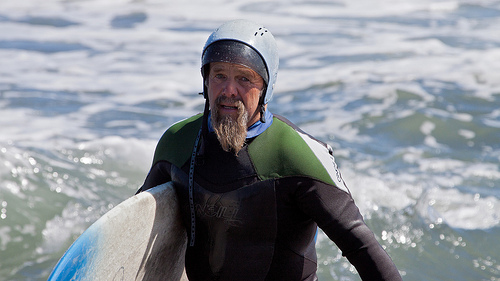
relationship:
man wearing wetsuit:
[139, 25, 402, 280] [132, 114, 401, 280]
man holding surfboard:
[139, 25, 402, 280] [48, 185, 189, 281]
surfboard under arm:
[48, 185, 189, 281] [139, 129, 168, 189]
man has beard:
[139, 25, 402, 280] [214, 110, 250, 154]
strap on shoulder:
[185, 113, 204, 245] [162, 122, 202, 153]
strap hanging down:
[185, 113, 204, 245] [192, 242, 193, 243]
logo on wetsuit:
[193, 198, 253, 221] [132, 114, 401, 280]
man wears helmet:
[139, 25, 402, 280] [196, 18, 276, 105]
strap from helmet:
[185, 113, 204, 245] [196, 18, 276, 105]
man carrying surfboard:
[139, 25, 402, 280] [48, 185, 189, 281]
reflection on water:
[4, 151, 114, 204] [1, 1, 497, 280]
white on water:
[5, 0, 497, 165] [1, 1, 497, 280]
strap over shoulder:
[185, 113, 204, 245] [162, 122, 202, 153]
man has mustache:
[139, 25, 402, 280] [213, 98, 250, 120]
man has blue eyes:
[139, 25, 402, 280] [216, 73, 260, 85]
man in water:
[139, 25, 402, 280] [1, 1, 497, 280]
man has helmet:
[139, 25, 402, 280] [196, 18, 276, 105]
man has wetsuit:
[139, 25, 402, 280] [132, 114, 401, 280]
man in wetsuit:
[139, 25, 402, 280] [132, 114, 401, 280]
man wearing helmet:
[139, 25, 402, 280] [196, 18, 276, 105]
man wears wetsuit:
[139, 25, 402, 280] [132, 114, 401, 280]